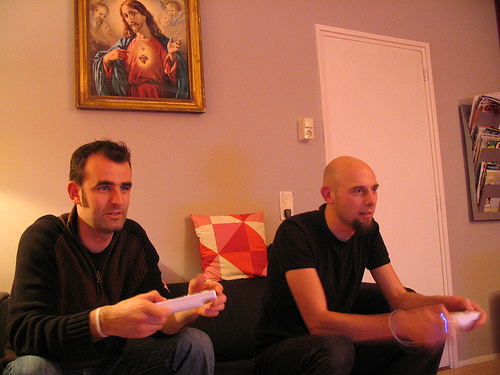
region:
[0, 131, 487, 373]
Tow men playing nintendo wii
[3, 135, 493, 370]
Tow men playing nintendo wii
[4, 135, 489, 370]
Tow men playing nintendo wii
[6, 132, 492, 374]
Tow men playing nintendo wii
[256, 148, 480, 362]
Man on right playing video game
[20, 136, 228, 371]
Man on left playing video game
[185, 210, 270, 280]
A pillow with pink and orange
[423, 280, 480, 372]
White remote control on right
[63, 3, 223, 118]
Picture of Jesus on wall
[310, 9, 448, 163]
A white door behind man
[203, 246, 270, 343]
A black couch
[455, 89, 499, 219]
A grey rack of magazines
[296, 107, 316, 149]
An off white thermostat control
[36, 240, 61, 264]
black fabric on sweater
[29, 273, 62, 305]
black fabric on sweater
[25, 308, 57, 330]
black fabric on sweater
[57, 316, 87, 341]
black fabric on sweater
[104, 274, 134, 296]
black fabric on sweater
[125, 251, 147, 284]
black fabric on sweater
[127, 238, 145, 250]
black fabric on sweater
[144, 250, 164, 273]
black fabric on sweater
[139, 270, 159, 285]
black fabric on sweater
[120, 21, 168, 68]
painting on the wall.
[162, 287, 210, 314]
controller in man's hands.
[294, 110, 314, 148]
thermostat on the wall.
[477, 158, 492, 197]
magazines in a rack.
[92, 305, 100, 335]
bracelet on man's wrist.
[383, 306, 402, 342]
cord of the controller.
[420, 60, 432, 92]
hinge of the door.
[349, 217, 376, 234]
goatee on man's face.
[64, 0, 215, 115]
painting on the wall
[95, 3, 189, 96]
picture of jesus on wall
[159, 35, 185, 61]
jesus' left hand in picture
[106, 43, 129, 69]
jesus' right hand in picture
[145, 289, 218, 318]
wii controller in hand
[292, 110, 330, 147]
white thermostat on wall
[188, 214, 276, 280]
pillow on the couch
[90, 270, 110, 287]
zipper on man's sweater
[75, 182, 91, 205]
the man's sideburn on face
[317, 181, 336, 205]
the man's right ear